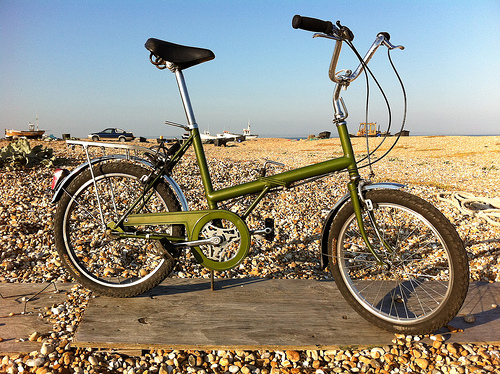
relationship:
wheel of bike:
[315, 182, 467, 336] [49, 14, 471, 335]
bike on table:
[49, 14, 471, 335] [88, 271, 484, 349]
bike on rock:
[49, 14, 471, 335] [11, 138, 485, 320]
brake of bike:
[375, 33, 407, 53] [49, 14, 471, 335]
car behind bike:
[87, 127, 137, 142] [49, 14, 471, 335]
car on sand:
[82, 124, 140, 142] [94, 139, 144, 153]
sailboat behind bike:
[8, 125, 43, 139] [72, 10, 439, 321]